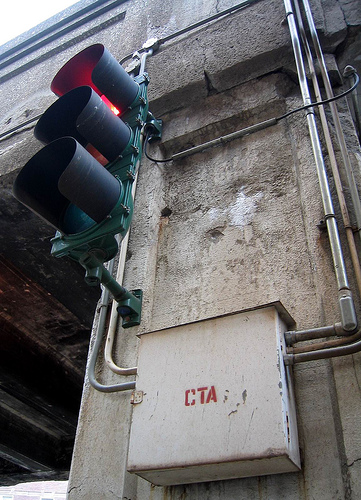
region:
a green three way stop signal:
[17, 41, 157, 277]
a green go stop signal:
[15, 136, 112, 227]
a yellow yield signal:
[36, 92, 122, 168]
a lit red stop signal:
[45, 43, 130, 113]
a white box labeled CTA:
[128, 298, 309, 486]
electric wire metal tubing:
[284, 23, 359, 363]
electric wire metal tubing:
[74, 185, 133, 392]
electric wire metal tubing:
[116, 0, 260, 75]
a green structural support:
[76, 256, 142, 322]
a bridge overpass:
[0, 0, 125, 482]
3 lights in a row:
[25, 45, 131, 250]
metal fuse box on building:
[136, 315, 303, 478]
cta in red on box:
[171, 379, 225, 426]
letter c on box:
[180, 387, 193, 409]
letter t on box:
[194, 385, 206, 406]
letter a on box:
[208, 387, 220, 404]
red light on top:
[61, 36, 144, 108]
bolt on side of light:
[118, 203, 131, 217]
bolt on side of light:
[119, 167, 134, 178]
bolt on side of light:
[126, 115, 143, 131]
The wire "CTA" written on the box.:
[163, 356, 250, 412]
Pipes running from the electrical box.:
[76, 297, 141, 400]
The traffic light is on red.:
[38, 50, 137, 114]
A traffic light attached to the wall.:
[36, 41, 121, 259]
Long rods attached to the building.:
[290, 70, 354, 296]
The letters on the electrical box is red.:
[179, 377, 221, 415]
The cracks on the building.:
[164, 50, 224, 96]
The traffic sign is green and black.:
[55, 49, 157, 320]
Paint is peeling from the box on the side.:
[271, 343, 295, 445]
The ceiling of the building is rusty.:
[20, 251, 93, 358]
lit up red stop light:
[81, 64, 141, 108]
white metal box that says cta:
[169, 381, 236, 417]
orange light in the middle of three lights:
[57, 106, 139, 164]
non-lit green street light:
[36, 164, 115, 239]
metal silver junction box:
[141, 37, 183, 69]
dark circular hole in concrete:
[159, 205, 193, 226]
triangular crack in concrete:
[196, 64, 236, 99]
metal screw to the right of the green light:
[118, 197, 139, 218]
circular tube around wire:
[163, 112, 292, 172]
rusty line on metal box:
[186, 445, 315, 479]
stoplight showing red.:
[48, 43, 139, 162]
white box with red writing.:
[122, 319, 316, 491]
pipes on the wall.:
[281, 49, 358, 221]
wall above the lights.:
[2, 12, 153, 101]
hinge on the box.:
[110, 391, 158, 415]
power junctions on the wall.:
[122, 41, 178, 84]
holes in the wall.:
[151, 200, 263, 258]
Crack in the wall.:
[195, 0, 257, 23]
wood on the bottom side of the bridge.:
[5, 247, 98, 482]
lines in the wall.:
[220, 344, 351, 497]